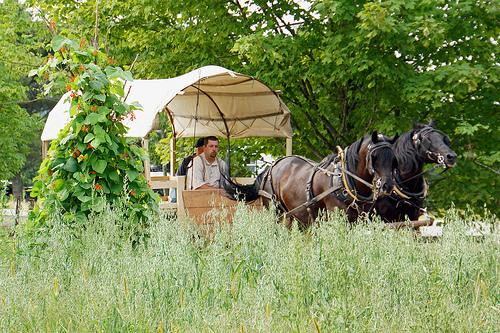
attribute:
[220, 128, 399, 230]
horse — forward facing, brown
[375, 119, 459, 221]
horse — black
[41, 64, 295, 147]
canopy — white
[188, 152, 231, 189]
shirt — white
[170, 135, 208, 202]
man — riding, sitting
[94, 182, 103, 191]
berries — red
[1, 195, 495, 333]
grass — tall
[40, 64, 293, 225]
wagon — covered, beige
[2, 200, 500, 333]
field — tall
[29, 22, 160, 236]
plant — tall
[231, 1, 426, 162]
tree — green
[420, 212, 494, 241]
truck — parked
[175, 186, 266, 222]
bench — brown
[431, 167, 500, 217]
shrubs — green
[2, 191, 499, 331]
bushes — tall